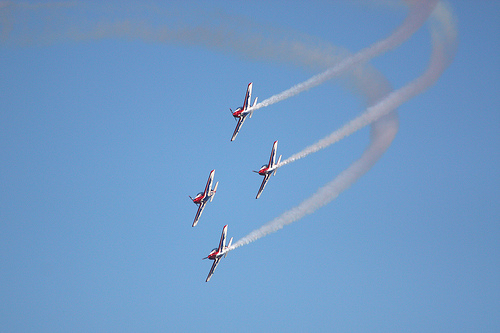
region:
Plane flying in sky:
[230, 82, 258, 144]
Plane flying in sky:
[253, 140, 281, 198]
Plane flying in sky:
[203, 227, 235, 283]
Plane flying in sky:
[189, 165, 221, 227]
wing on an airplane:
[241, 83, 253, 105]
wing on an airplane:
[227, 117, 249, 144]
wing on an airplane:
[264, 140, 282, 167]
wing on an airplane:
[256, 173, 273, 200]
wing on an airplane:
[205, 257, 220, 282]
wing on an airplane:
[218, 223, 230, 250]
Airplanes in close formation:
[185, 72, 291, 285]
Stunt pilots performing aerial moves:
[186, 79, 300, 292]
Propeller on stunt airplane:
[186, 193, 201, 208]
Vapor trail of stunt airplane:
[270, 15, 467, 183]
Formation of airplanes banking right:
[185, 77, 289, 292]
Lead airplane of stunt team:
[185, 167, 228, 229]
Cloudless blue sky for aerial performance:
[7, 5, 496, 329]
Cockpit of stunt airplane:
[191, 188, 206, 199]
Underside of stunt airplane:
[202, 226, 235, 284]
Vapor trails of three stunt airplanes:
[232, 11, 479, 265]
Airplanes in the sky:
[188, 82, 281, 277]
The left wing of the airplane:
[216, 227, 231, 251]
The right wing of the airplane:
[255, 175, 270, 199]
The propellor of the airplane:
[190, 193, 197, 205]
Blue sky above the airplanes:
[1, 1, 497, 331]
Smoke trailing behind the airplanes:
[228, 2, 458, 258]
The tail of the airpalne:
[274, 152, 281, 174]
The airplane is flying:
[206, 223, 233, 279]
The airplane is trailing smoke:
[203, 229, 230, 279]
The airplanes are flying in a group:
[188, 83, 280, 280]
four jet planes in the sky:
[172, 51, 314, 310]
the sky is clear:
[119, 115, 181, 275]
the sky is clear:
[51, 30, 156, 217]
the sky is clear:
[351, 143, 486, 315]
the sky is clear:
[391, 276, 444, 331]